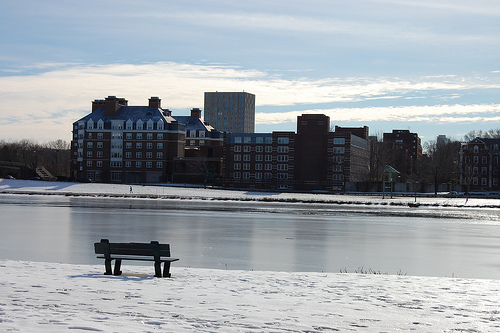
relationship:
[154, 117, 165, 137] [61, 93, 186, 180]
window of building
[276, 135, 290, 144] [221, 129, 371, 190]
window of building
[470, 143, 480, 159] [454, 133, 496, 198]
window of building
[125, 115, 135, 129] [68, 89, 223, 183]
window of building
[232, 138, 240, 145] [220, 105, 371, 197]
window of building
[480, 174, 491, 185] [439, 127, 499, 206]
window of building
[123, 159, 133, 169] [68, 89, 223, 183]
window of building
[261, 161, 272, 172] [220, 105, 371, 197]
window of building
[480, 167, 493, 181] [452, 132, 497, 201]
window of building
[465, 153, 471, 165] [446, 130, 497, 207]
window of building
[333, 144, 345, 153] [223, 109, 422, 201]
window of building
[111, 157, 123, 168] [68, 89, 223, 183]
window of building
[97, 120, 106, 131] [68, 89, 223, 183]
window of building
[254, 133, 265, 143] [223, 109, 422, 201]
window of building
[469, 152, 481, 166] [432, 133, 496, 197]
window of building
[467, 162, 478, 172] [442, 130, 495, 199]
window of building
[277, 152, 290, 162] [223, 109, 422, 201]
window of building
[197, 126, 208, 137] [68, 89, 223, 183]
window of building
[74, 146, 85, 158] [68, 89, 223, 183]
window of building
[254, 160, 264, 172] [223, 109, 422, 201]
window of building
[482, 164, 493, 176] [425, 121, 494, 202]
window of building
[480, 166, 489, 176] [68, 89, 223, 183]
window of building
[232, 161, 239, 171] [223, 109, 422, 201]
window of building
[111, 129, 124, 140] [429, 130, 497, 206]
window of building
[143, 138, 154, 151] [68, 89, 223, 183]
window of building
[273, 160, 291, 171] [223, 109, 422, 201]
window of building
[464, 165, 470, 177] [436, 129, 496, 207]
window of building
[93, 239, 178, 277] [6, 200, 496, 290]
bench by river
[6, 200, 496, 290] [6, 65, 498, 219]
river looking at city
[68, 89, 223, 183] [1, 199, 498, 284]
building across water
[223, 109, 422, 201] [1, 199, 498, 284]
building across water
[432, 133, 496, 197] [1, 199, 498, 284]
building across water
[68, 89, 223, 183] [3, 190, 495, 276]
building across water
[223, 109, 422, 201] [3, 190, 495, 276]
building across water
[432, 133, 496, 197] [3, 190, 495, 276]
building across water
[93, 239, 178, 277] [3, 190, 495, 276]
bench by water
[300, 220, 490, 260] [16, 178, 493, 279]
water on river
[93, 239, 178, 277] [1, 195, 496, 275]
bench near river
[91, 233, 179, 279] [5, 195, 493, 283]
bench near body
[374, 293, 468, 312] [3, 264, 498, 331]
snow on ground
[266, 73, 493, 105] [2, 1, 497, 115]
clouds in sky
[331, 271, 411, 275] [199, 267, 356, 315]
grass in snow